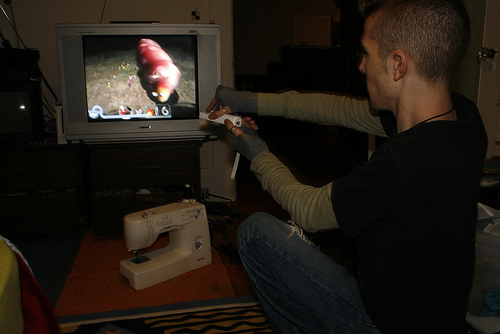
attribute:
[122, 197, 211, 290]
machine — white, sewing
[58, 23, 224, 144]
tv — silver, on, gray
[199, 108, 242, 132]
control — white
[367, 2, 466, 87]
haircut — short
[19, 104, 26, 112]
knob — silver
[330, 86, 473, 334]
shirt — black, short sleeve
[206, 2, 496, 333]
man — involved, sitting, inside, crouched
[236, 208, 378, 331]
jeans — ripped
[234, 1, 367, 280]
section — dark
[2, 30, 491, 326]
area — congested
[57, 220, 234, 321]
rug — red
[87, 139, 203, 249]
stand — black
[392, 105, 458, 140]
necklace — black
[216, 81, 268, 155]
gloves — gray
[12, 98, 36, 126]
light — reflecting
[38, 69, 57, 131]
cords — plugged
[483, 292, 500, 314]
rag — teal